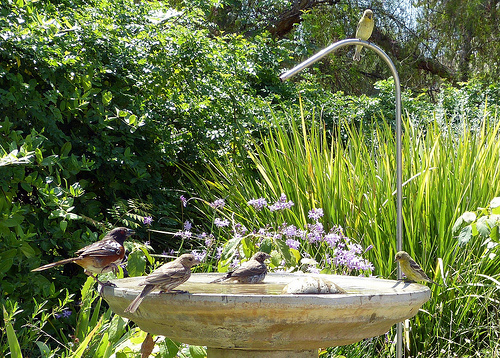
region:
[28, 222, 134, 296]
a perching bird with red breast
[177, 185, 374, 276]
a group of small purple flowers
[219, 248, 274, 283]
a small brown bird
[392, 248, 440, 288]
a small bird with yellow breast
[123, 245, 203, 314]
a bird perching with long tail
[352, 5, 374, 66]
a yellow bird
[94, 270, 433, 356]
a stone bird bath basin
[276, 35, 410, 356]
a tall metal water spout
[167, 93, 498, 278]
a group of tall, green grass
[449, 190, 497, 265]
flat green leaves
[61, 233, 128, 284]
bird on edge of bird bath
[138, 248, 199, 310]
bird on edge of bird bath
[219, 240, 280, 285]
bird in the water of bird bath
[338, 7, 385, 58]
bird on top of the faucet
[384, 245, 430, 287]
bird on the edge of bird bath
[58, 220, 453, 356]
4 birds in bird bath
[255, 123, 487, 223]
tall green grassy plant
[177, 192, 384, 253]
tall purple flowers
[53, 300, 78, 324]
purple flower peeking through bushes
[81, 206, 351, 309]
birds on wooden birdbath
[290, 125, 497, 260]
tall grass behind birdbath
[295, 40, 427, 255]
metal fountain over birdbath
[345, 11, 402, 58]
bird sitting on metal pipe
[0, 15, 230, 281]
green bushes left of grass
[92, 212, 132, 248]
bird has brown head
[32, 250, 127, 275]
bird has long tail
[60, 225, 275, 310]
birds sitting on edge of birdbath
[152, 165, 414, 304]
lavender flowers behind birds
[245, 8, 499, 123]
tall trees in distance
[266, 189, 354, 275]
purple flowers next to the bird bath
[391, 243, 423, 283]
yelloow bird next to the faucet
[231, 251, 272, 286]
bird sitting in the water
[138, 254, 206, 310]
brown bird sitting on the edge of bird bath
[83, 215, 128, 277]
black and red bird has it's claw up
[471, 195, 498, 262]
white flowers behind the faucet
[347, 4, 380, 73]
yellow bird sitting on the faucet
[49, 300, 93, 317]
blue flowers under the bird's tail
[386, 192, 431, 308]
faucet is next to the bird bath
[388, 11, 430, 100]
trees behind the yellow bird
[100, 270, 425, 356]
bird bath in a garden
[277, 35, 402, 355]
fountain pipe over the bird bath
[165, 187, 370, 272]
purple flowers growing next to the bird bath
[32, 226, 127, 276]
sparrow sitting on the bird bath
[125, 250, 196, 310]
bird on the rim of the bird bath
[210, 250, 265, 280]
bird bathing in the bird bath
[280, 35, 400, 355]
silver fountain pipe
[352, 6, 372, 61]
bird sitting on the fountain pipe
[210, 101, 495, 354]
tall green grass behind the bird bath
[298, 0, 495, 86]
large tree in the background